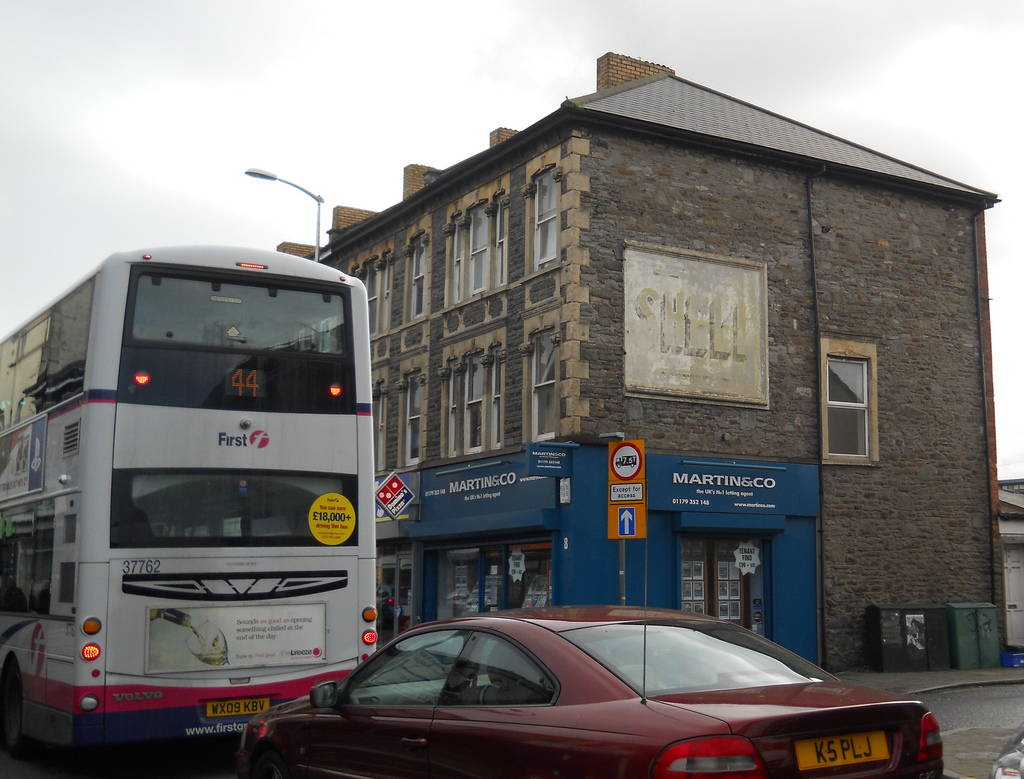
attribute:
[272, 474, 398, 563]
circle — yellow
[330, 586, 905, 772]
car — burgundy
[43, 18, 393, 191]
sky — cloudy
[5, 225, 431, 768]
bus — double decker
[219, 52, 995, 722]
office block — tall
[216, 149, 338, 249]
street lighting — high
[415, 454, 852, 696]
shop establishment — blue painted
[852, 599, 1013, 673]
litter bins — on the right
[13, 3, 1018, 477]
sky — sparsely clouded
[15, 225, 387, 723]
bus — double decker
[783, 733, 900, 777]
plate numbers — car's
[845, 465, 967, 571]
brick — dark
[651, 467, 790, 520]
writing — white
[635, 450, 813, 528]
background — blue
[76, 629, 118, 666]
light — red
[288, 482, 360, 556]
sign — yellow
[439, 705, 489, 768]
bus — white, double decker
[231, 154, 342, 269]
street light — on top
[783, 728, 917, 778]
license plate — european, bright yellow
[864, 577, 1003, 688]
structures — few, locked, metal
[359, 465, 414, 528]
restaurant sign — three dimensional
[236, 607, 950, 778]
sedan — red, saloon, small